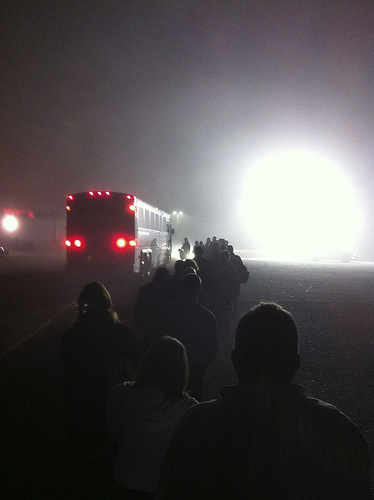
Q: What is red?
A: Lights.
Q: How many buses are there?
A: One.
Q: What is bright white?
A: An illumination.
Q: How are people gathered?
A: In a line.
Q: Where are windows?
A: On a bus.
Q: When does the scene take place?
A: Night.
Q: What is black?
A: Sky.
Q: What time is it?
A: Night.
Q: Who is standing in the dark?
A: A man.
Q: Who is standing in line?
A: Many people.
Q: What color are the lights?
A: Red.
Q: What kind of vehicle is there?
A: A bus.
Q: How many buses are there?
A: One.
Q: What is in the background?
A: A bright light.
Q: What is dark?
A: The ground.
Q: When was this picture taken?
A: During the night.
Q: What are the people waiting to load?
A: A bus.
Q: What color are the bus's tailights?
A: Red.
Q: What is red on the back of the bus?
A: The lights.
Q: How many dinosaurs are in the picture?
A: Zero.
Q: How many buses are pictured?
A: One.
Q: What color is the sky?
A: Black.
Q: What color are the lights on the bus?
A: Red.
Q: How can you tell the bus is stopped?
A: The brake lights are on.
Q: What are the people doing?
A: Waiting to get on the bus.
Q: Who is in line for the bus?
A: Many people.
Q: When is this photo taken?
A: At nighttime.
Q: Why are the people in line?
A: They are waiting to get on the bus.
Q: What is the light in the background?
A: A spot light.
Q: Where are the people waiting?
A: At a bus station.